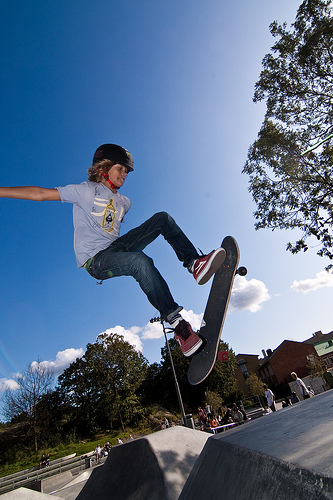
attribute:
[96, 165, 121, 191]
chin strap — red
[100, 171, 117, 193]
strap — red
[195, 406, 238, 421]
people — sitting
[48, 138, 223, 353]
boy — balancing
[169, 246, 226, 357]
snickers — red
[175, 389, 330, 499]
skateboard ramp — cement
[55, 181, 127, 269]
blue teeshirt — light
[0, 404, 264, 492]
stands — long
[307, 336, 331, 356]
roof — green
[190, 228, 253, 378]
skateboard — black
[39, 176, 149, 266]
shirt — orange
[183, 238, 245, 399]
skate board — black, tan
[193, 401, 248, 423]
people — background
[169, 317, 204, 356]
sneaker — red, white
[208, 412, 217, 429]
person — wearing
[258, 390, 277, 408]
shirt — white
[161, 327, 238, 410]
trees — tall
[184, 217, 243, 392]
skate board — black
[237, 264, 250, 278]
wheel — red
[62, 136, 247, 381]
person — walking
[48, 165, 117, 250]
shirt — white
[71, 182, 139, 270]
shirt — gray, cotton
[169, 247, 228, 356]
skate shoes — red, white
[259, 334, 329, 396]
building — red, brick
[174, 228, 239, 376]
sneakers — red